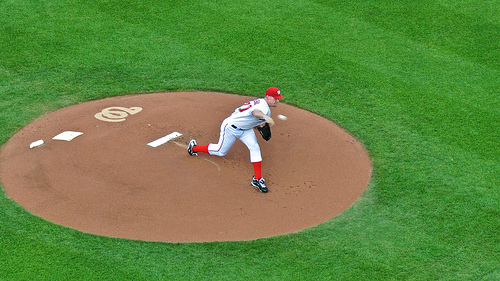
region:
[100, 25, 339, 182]
a baseball player pitching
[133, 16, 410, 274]
a baseball player in the pitcher's circle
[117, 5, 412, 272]
baseball player on baseball field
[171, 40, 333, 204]
a red and white uniform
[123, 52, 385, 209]
red and white baseball uniform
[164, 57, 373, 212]
a baseball player wearing a uniform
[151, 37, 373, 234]
a man playing baseball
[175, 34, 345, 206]
a man pitching a baseball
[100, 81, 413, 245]
a man throwing a baseball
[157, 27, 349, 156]
a man in a red and white uniform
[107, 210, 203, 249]
section of red circular mound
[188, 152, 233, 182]
white spot on mound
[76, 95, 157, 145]
logo on mound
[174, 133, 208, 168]
black and white sneakers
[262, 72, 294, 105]
red cap with white logo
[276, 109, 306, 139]
white baseball in the air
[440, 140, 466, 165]
tiny white spot on the grass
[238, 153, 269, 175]
man wearing red socks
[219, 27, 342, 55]
well manicured grass on the field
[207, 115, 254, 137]
belt loops around pants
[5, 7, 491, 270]
This is a baseball game.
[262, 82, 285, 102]
The baseball hat is red.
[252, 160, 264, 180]
The players socks are red.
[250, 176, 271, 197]
The players shoes are black.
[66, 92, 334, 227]
This is a pitchers mound.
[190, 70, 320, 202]
This position is known as the pitcher.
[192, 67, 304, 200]
The player is throwing the ball.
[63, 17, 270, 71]
The color of the grass is green.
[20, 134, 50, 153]
This is a chalk bag.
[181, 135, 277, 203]
The player wears baseball cleats.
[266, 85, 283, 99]
the red hat on the baseball player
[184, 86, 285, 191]
the baseball player standing on dirt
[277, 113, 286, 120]
the white baseball in mid air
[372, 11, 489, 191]
the nice green grass on the field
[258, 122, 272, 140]
the baseball glove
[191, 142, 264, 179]
the red knee high socks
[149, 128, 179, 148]
the white mark on the dirt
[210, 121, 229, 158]
the stripe on the pants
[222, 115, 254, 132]
the belt on the pants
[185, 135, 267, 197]
the baseball shoes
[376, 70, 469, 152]
the AstroTurf is green in color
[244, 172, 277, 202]
the shoe is black and white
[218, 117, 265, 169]
the pants are white and red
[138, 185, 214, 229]
the pitchers mound is brown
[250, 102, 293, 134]
the pitcher threw with his right arm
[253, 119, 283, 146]
the glove is black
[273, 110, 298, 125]
the baseball is blurry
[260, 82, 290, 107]
the hat is red and white in color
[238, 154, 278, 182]
the socks are red in color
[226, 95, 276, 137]
the jersey is white and red